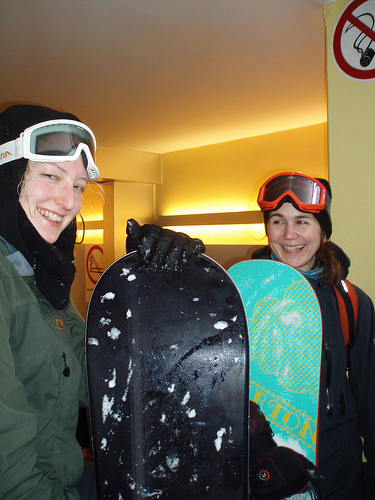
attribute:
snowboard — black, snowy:
[80, 244, 252, 499]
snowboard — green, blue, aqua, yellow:
[218, 254, 323, 499]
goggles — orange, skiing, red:
[255, 171, 331, 223]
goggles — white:
[0, 116, 104, 179]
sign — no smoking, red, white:
[335, 4, 372, 80]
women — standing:
[3, 98, 374, 499]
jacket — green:
[4, 239, 98, 495]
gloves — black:
[122, 218, 203, 273]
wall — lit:
[323, 4, 375, 276]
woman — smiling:
[218, 160, 374, 498]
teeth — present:
[38, 207, 66, 226]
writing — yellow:
[251, 385, 316, 453]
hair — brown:
[317, 220, 355, 286]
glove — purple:
[244, 407, 305, 498]